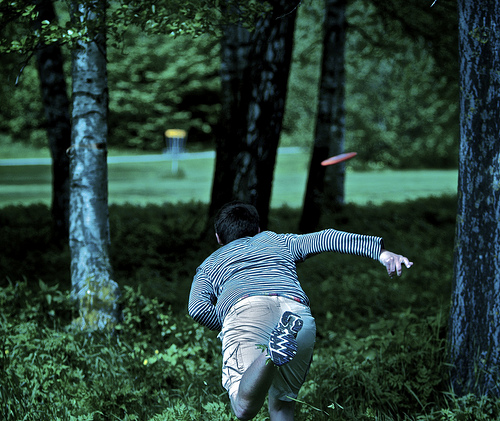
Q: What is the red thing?
A: Frisbee.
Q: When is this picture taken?
A: Daytime.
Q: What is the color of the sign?
A: Yellow.